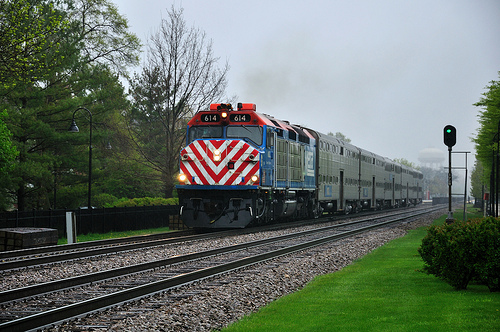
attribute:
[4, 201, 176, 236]
fence — black colored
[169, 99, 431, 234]
train — red, white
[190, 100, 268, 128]
numbers — train, 614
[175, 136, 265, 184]
chevron pattern — red, white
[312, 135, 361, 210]
train car — gray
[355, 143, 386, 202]
train car — gray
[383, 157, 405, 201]
train car — gray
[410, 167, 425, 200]
train car — gray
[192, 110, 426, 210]
train — striped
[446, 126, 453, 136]
light — green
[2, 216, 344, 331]
tracks — metal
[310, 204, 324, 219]
wheel — train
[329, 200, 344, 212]
wheel — train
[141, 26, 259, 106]
tree — leafless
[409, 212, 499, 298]
bush — green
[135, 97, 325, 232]
engine — red, white, blue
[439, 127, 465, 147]
traffic light — green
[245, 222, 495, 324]
space — green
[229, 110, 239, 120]
number — 6